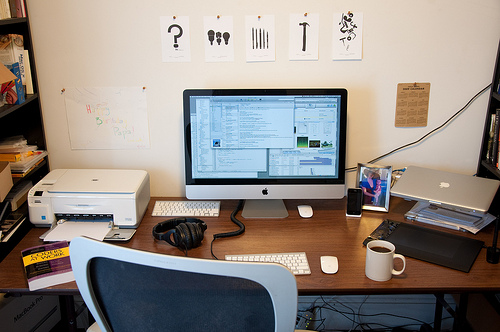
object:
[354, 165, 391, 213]
picture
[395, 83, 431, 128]
calendar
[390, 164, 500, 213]
laptop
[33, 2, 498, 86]
wall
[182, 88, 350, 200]
computer monitor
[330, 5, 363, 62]
paper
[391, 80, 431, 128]
paper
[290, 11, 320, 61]
paper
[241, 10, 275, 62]
paper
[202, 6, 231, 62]
paper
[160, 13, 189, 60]
paper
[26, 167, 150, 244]
printer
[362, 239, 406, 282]
cup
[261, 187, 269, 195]
logo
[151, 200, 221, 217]
keyboard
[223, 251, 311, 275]
keyboard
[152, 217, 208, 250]
headphone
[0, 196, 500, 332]
desk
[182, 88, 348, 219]
computer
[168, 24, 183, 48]
question mark